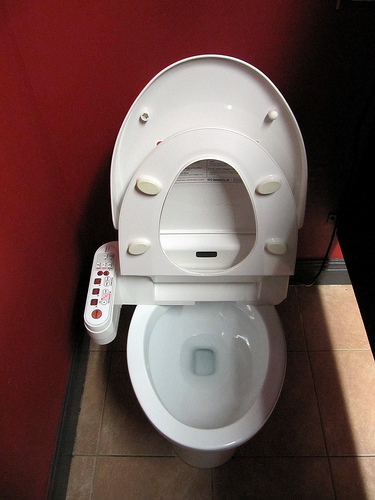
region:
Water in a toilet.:
[173, 330, 233, 385]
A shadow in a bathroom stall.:
[209, 278, 369, 496]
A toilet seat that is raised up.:
[114, 126, 298, 278]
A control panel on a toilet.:
[86, 239, 119, 325]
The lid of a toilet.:
[104, 52, 310, 233]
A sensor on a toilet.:
[186, 246, 224, 261]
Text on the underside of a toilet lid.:
[173, 156, 245, 185]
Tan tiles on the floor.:
[64, 281, 373, 499]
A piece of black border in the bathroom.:
[321, 257, 352, 290]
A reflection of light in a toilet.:
[229, 330, 254, 348]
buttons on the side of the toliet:
[84, 252, 115, 332]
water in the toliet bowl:
[182, 330, 224, 388]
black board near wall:
[58, 380, 79, 427]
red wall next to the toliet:
[24, 269, 57, 362]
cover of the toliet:
[149, 61, 258, 113]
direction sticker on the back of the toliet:
[187, 173, 228, 186]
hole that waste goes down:
[193, 339, 215, 378]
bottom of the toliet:
[188, 455, 229, 472]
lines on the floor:
[84, 444, 119, 470]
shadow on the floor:
[316, 294, 353, 346]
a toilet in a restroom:
[53, 43, 332, 473]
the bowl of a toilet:
[128, 304, 290, 448]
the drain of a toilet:
[194, 348, 212, 376]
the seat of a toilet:
[121, 127, 295, 279]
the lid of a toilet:
[114, 55, 303, 133]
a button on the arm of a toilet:
[89, 308, 102, 319]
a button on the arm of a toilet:
[89, 295, 99, 305]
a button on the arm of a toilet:
[94, 276, 102, 285]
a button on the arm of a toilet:
[97, 269, 102, 274]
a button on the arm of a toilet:
[100, 299, 106, 305]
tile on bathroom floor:
[64, 281, 374, 497]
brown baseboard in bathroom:
[284, 258, 348, 284]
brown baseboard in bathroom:
[44, 318, 90, 498]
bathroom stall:
[331, 2, 373, 357]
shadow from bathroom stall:
[70, 83, 365, 498]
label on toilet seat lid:
[153, 135, 261, 183]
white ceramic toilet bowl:
[124, 303, 284, 463]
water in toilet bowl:
[177, 332, 226, 385]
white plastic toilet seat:
[117, 126, 295, 276]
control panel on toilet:
[84, 239, 118, 342]